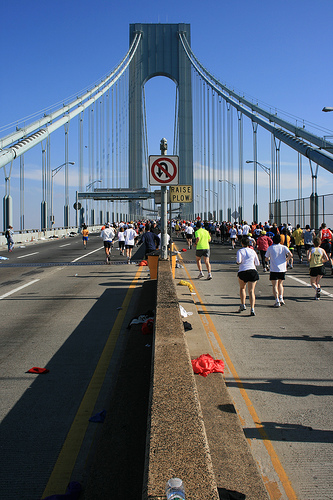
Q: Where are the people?
A: On a bridge.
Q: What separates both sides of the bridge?
A: A median.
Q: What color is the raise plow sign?
A: Yellow with black words.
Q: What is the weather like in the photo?
A: Sunny.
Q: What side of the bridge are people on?
A: Both sides.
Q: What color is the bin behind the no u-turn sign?
A: Yellow and black.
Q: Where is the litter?
A: On the ground.